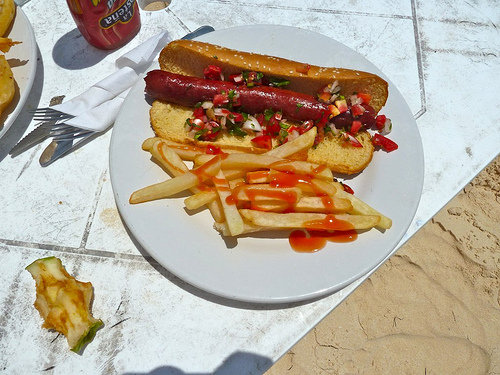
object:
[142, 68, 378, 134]
hot dog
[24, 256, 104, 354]
apple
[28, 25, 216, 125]
forks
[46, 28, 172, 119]
napkin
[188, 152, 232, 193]
ketchup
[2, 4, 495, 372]
top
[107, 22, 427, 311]
plate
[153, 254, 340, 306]
edge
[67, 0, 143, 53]
half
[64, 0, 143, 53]
bottle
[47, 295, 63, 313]
brown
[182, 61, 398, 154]
fixings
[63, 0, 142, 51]
ketchup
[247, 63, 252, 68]
sesame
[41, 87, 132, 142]
fork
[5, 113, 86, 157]
knife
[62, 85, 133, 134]
paper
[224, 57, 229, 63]
sesame seeds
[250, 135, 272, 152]
pico de-gallo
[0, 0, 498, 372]
table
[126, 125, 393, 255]
food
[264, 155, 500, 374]
sand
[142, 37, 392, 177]
bun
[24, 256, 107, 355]
apple core